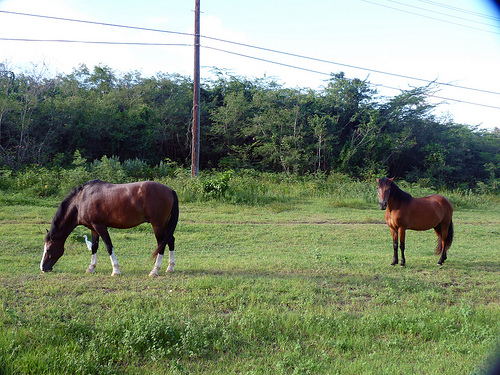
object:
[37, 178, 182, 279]
horse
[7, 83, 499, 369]
field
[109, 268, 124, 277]
foot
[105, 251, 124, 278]
sock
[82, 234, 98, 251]
bird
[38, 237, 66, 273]
face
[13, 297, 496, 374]
grass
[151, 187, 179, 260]
tail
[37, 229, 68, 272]
head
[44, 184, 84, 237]
mane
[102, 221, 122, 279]
left front foot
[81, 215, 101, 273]
right front foot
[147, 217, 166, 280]
left back leg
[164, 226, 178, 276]
right back leg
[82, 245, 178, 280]
hooves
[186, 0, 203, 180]
pole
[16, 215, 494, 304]
ground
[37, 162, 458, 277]
two horses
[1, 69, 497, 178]
trees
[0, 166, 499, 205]
bushes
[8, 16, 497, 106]
telephone wires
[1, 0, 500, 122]
sky